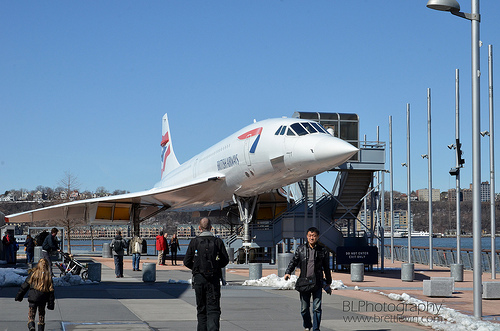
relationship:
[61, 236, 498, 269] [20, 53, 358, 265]
waterway behind jet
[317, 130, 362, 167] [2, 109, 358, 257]
nose of jet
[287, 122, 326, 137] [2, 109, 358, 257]
cockpit of jet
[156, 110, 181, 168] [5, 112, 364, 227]
tail-fin of jet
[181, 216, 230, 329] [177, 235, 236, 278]
man wearing coat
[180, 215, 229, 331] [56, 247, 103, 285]
man holding trolley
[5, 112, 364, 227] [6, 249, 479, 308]
jet on tarmac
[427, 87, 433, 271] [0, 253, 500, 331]
steel poles standing on tarmac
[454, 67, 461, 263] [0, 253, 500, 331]
steel poles standing on tarmac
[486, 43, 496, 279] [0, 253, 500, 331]
steel poles standing on tarmac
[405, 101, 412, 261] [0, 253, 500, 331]
steel poles standing on tarmac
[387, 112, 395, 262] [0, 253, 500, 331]
steel poles standing on tarmac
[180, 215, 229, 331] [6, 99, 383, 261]
man walking away from plane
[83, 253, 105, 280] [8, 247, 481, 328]
can on ground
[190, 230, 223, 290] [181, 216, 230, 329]
backpack on man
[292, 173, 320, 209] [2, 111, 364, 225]
stairway going up to jet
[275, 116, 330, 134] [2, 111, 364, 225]
windows on jet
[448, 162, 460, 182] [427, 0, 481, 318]
light on pole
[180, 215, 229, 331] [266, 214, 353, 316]
man wearing jacket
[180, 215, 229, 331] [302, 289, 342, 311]
man has jeans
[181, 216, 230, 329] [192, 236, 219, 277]
man carrying backpack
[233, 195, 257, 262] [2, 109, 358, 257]
landing gear of jet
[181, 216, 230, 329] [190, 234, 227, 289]
man wearing a backpack